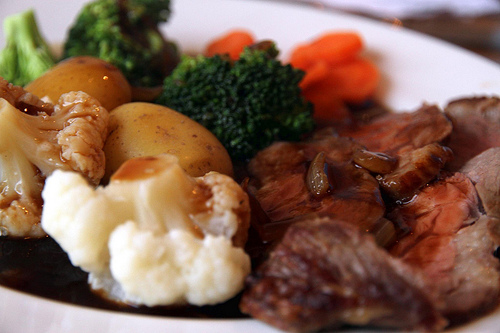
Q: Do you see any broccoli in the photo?
A: Yes, there is broccoli.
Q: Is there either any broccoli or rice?
A: Yes, there is broccoli.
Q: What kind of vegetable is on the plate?
A: The vegetable is broccoli.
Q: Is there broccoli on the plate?
A: Yes, there is broccoli on the plate.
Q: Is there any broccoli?
A: Yes, there is broccoli.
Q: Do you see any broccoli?
A: Yes, there is broccoli.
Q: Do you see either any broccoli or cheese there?
A: Yes, there is broccoli.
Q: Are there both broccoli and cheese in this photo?
A: No, there is broccoli but no cheese.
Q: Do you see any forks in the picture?
A: No, there are no forks.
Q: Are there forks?
A: No, there are no forks.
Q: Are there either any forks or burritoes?
A: No, there are no forks or burritoes.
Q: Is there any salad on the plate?
A: No, there is broccoli on the plate.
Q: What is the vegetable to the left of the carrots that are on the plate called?
A: The vegetable is broccoli.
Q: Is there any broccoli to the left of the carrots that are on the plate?
A: Yes, there is broccoli to the left of the carrots.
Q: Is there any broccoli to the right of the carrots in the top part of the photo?
A: No, the broccoli is to the left of the carrots.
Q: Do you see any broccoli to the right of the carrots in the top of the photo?
A: No, the broccoli is to the left of the carrots.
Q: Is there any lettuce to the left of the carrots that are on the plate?
A: No, there is broccoli to the left of the carrots.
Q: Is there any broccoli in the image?
A: Yes, there is broccoli.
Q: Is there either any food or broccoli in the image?
A: Yes, there is broccoli.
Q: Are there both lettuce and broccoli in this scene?
A: No, there is broccoli but no lettuce.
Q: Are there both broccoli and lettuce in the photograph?
A: No, there is broccoli but no lettuce.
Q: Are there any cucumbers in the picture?
A: No, there are no cucumbers.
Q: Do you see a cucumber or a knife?
A: No, there are no cucumbers or knives.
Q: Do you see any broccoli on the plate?
A: Yes, there is broccoli on the plate.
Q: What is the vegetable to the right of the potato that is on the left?
A: The vegetable is broccoli.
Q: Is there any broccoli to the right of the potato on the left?
A: Yes, there is broccoli to the right of the potato.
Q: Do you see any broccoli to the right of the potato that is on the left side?
A: Yes, there is broccoli to the right of the potato.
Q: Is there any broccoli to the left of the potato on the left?
A: No, the broccoli is to the right of the potato.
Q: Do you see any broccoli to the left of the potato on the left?
A: No, the broccoli is to the right of the potato.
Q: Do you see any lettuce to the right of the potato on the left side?
A: No, there is broccoli to the right of the potato.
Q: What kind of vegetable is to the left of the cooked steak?
A: The vegetable is broccoli.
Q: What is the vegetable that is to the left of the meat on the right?
A: The vegetable is broccoli.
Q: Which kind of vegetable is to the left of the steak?
A: The vegetable is broccoli.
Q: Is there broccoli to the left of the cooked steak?
A: Yes, there is broccoli to the left of the steak.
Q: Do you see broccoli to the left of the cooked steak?
A: Yes, there is broccoli to the left of the steak.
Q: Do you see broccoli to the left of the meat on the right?
A: Yes, there is broccoli to the left of the steak.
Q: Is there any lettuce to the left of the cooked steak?
A: No, there is broccoli to the left of the steak.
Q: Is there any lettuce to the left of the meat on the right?
A: No, there is broccoli to the left of the steak.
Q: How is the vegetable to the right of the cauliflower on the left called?
A: The vegetable is broccoli.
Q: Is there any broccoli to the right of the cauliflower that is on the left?
A: Yes, there is broccoli to the right of the cauliflower.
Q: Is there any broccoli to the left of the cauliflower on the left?
A: No, the broccoli is to the right of the cauliflower.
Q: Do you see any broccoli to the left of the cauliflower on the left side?
A: No, the broccoli is to the right of the cauliflower.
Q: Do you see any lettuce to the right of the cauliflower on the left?
A: No, there is broccoli to the right of the cauliflower.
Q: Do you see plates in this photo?
A: Yes, there is a plate.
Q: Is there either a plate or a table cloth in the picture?
A: Yes, there is a plate.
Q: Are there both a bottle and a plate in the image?
A: No, there is a plate but no bottles.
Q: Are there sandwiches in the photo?
A: No, there are no sandwiches.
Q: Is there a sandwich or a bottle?
A: No, there are no sandwiches or bottles.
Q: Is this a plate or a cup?
A: This is a plate.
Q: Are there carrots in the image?
A: Yes, there are carrots.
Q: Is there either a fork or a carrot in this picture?
A: Yes, there are carrots.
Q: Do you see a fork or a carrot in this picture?
A: Yes, there are carrots.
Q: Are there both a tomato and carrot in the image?
A: No, there are carrots but no tomatoes.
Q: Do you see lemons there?
A: No, there are no lemons.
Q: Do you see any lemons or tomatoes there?
A: No, there are no lemons or tomatoes.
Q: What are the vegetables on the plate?
A: The vegetables are carrots.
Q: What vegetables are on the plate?
A: The vegetables are carrots.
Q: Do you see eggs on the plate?
A: No, there are carrots on the plate.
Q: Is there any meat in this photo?
A: Yes, there is meat.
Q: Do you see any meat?
A: Yes, there is meat.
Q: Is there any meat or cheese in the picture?
A: Yes, there is meat.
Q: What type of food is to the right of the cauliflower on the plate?
A: The food is meat.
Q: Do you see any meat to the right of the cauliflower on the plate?
A: Yes, there is meat to the right of the cauliflower.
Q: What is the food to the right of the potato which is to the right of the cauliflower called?
A: The food is meat.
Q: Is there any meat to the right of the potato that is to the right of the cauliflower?
A: Yes, there is meat to the right of the potato.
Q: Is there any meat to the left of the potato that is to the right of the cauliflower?
A: No, the meat is to the right of the potato.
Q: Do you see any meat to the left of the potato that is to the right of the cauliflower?
A: No, the meat is to the right of the potato.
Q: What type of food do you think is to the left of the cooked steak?
A: The food is meat.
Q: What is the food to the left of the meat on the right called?
A: The food is meat.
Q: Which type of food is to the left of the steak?
A: The food is meat.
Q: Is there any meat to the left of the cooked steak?
A: Yes, there is meat to the left of the steak.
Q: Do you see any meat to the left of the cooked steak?
A: Yes, there is meat to the left of the steak.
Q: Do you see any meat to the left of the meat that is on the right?
A: Yes, there is meat to the left of the steak.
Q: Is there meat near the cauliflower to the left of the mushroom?
A: Yes, there is meat near the cauliflower.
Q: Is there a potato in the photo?
A: Yes, there is a potato.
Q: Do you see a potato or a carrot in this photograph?
A: Yes, there is a potato.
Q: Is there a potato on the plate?
A: Yes, there is a potato on the plate.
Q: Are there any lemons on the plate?
A: No, there is a potato on the plate.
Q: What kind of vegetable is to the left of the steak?
A: The vegetable is a potato.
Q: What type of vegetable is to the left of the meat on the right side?
A: The vegetable is a potato.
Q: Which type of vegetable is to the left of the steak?
A: The vegetable is a potato.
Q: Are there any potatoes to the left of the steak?
A: Yes, there is a potato to the left of the steak.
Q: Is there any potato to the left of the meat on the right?
A: Yes, there is a potato to the left of the steak.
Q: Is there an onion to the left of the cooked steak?
A: No, there is a potato to the left of the steak.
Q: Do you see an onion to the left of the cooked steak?
A: No, there is a potato to the left of the steak.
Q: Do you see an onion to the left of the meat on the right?
A: No, there is a potato to the left of the steak.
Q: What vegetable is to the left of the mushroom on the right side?
A: The vegetable is a potato.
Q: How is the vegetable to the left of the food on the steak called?
A: The vegetable is a potato.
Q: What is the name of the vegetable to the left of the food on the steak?
A: The vegetable is a potato.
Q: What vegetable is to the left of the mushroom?
A: The vegetable is a potato.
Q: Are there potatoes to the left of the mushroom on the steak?
A: Yes, there is a potato to the left of the mushroom.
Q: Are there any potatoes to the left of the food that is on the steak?
A: Yes, there is a potato to the left of the mushroom.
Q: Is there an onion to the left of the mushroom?
A: No, there is a potato to the left of the mushroom.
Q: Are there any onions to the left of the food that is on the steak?
A: No, there is a potato to the left of the mushroom.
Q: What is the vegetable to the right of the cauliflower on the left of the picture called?
A: The vegetable is a potato.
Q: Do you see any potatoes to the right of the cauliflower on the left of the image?
A: Yes, there is a potato to the right of the cauliflower.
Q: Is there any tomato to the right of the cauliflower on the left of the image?
A: No, there is a potato to the right of the cauliflower.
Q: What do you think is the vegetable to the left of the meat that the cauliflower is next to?
A: The vegetable is a potato.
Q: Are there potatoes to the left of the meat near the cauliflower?
A: Yes, there is a potato to the left of the meat.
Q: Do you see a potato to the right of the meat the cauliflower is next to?
A: No, the potato is to the left of the meat.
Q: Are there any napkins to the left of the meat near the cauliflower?
A: No, there is a potato to the left of the meat.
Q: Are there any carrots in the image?
A: Yes, there are carrots.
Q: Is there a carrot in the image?
A: Yes, there are carrots.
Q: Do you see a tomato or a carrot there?
A: Yes, there are carrots.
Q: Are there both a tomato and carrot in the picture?
A: No, there are carrots but no tomatoes.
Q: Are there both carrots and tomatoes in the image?
A: No, there are carrots but no tomatoes.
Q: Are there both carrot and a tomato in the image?
A: No, there are carrots but no tomatoes.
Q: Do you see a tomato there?
A: No, there are no tomatoes.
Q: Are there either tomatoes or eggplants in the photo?
A: No, there are no tomatoes or eggplants.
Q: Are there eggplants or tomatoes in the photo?
A: No, there are no tomatoes or eggplants.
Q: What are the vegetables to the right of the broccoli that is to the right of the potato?
A: The vegetables are carrots.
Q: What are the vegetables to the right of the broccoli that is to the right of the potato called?
A: The vegetables are carrots.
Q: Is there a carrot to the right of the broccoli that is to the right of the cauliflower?
A: Yes, there are carrots to the right of the broccoli.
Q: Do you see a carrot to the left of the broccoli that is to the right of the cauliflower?
A: No, the carrots are to the right of the broccoli.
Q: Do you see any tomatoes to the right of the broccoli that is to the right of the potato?
A: No, there are carrots to the right of the broccoli.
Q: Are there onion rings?
A: No, there are no onion rings.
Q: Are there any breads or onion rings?
A: No, there are no onion rings or breads.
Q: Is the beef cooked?
A: Yes, the beef is cooked.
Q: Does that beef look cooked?
A: Yes, the beef is cooked.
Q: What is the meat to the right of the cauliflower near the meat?
A: The meat is beef.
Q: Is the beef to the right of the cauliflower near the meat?
A: Yes, the beef is to the right of the cauliflower.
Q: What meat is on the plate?
A: The meat is beef.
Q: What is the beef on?
A: The beef is on the plate.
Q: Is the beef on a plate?
A: Yes, the beef is on a plate.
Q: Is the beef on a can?
A: No, the beef is on a plate.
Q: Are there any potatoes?
A: Yes, there is a potato.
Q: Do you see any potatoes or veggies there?
A: Yes, there is a potato.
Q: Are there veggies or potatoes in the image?
A: Yes, there is a potato.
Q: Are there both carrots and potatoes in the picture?
A: Yes, there are both a potato and a carrot.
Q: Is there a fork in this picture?
A: No, there are no forks.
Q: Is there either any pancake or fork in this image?
A: No, there are no forks or pancakes.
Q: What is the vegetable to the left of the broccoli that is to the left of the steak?
A: The vegetable is a potato.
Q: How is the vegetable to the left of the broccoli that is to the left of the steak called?
A: The vegetable is a potato.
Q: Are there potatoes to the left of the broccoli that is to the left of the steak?
A: Yes, there is a potato to the left of the broccoli.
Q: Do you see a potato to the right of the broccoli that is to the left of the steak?
A: No, the potato is to the left of the broccoli.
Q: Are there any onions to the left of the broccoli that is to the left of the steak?
A: No, there is a potato to the left of the broccoli.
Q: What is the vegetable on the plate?
A: The vegetable is a potato.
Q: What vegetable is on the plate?
A: The vegetable is a potato.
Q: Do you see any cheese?
A: No, there is no cheese.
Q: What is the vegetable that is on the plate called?
A: The vegetable is cauliflower.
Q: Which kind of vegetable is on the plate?
A: The vegetable is cauliflower.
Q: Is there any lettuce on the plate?
A: No, there is cauliflower on the plate.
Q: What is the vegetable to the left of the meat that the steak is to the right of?
A: The vegetable is cauliflower.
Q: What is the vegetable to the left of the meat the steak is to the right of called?
A: The vegetable is cauliflower.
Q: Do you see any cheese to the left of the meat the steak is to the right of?
A: No, there is cauliflower to the left of the meat.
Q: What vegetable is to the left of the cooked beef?
A: The vegetable is cauliflower.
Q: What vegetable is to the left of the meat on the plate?
A: The vegetable is cauliflower.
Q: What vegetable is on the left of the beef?
A: The vegetable is cauliflower.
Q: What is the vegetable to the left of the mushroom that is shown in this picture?
A: The vegetable is cauliflower.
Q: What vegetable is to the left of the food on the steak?
A: The vegetable is cauliflower.